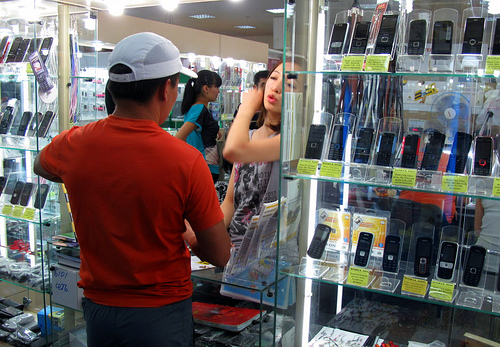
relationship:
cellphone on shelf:
[307, 224, 331, 259] [290, 260, 496, 315]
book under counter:
[192, 300, 266, 332] [192, 254, 293, 344]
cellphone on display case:
[460, 16, 487, 55] [270, 0, 498, 346]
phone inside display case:
[410, 231, 437, 280] [270, 0, 498, 346]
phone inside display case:
[414, 237, 434, 277] [270, 0, 498, 346]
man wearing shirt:
[8, 40, 238, 345] [52, 110, 247, 333]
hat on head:
[106, 27, 192, 98] [82, 29, 234, 149]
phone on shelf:
[351, 223, 373, 268] [285, 6, 485, 343]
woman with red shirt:
[178, 67, 225, 191] [38, 114, 222, 308]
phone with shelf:
[304, 124, 326, 160] [254, 13, 497, 339]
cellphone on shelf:
[303, 218, 330, 265] [290, 260, 496, 315]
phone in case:
[356, 124, 366, 171] [21, 48, 49, 235]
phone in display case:
[372, 3, 402, 60] [270, 0, 498, 346]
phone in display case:
[303, 120, 326, 160] [270, 0, 498, 346]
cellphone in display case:
[461, 17, 486, 54] [270, 0, 498, 346]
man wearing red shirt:
[33, 32, 230, 347] [38, 114, 222, 308]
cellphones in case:
[291, 5, 498, 296] [284, 1, 485, 340]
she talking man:
[222, 56, 307, 277] [33, 32, 230, 347]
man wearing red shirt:
[33, 32, 230, 347] [24, 110, 234, 317]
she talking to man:
[220, 56, 307, 265] [33, 32, 230, 347]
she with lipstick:
[220, 56, 307, 265] [261, 90, 276, 102]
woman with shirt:
[175, 69, 223, 184] [36, 118, 220, 303]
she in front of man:
[220, 56, 307, 265] [8, 40, 238, 345]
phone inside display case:
[319, 127, 451, 212] [262, 177, 352, 325]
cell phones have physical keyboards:
[305, 11, 499, 285] [321, 244, 384, 303]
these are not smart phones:
[232, 159, 497, 340] [302, 7, 491, 343]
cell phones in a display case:
[326, 21, 350, 54] [284, 241, 434, 347]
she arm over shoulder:
[220, 56, 307, 265] [224, 162, 250, 236]